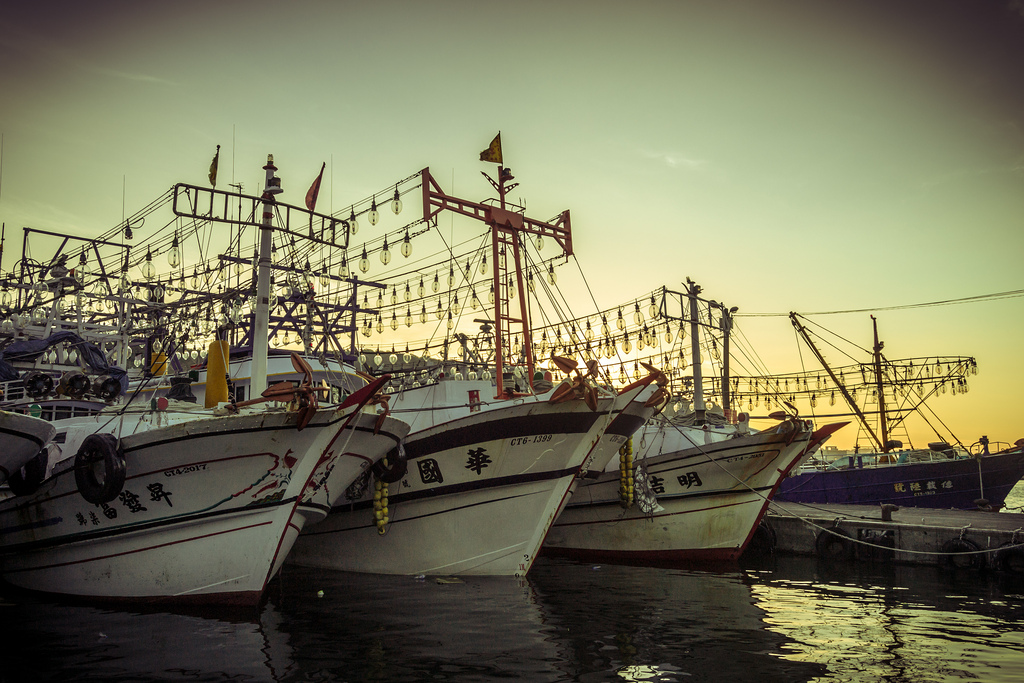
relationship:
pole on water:
[681, 282, 705, 416] [4, 528, 1011, 680]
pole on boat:
[681, 282, 704, 416] [557, 283, 843, 582]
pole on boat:
[681, 282, 705, 416] [768, 292, 1022, 515]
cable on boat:
[725, 310, 974, 462] [768, 292, 1022, 515]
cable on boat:
[563, 289, 728, 439] [569, 263, 838, 567]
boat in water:
[0, 141, 410, 621] [4, 528, 1011, 680]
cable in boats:
[725, 310, 974, 462] [40, 376, 824, 573]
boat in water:
[0, 141, 410, 621] [17, 560, 1017, 675]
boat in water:
[301, 361, 671, 597] [4, 528, 1011, 680]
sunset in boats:
[509, 311, 978, 452] [2, 275, 1020, 580]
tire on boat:
[1, 433, 50, 497] [40, 247, 401, 618]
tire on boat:
[369, 444, 406, 482] [0, 141, 410, 621]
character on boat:
[463, 447, 493, 476] [0, 141, 410, 621]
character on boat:
[463, 447, 493, 476] [48, 210, 415, 612]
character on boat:
[463, 447, 493, 476] [304, 137, 649, 577]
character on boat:
[463, 447, 493, 476] [320, 172, 650, 584]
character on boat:
[677, 468, 704, 495] [557, 283, 843, 582]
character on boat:
[463, 447, 493, 476] [557, 283, 843, 582]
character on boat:
[463, 447, 493, 476] [26, 162, 413, 589]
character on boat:
[463, 447, 493, 476] [725, 276, 1009, 574]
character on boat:
[463, 447, 493, 476] [309, 135, 612, 593]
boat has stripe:
[0, 141, 410, 621] [360, 454, 589, 526]